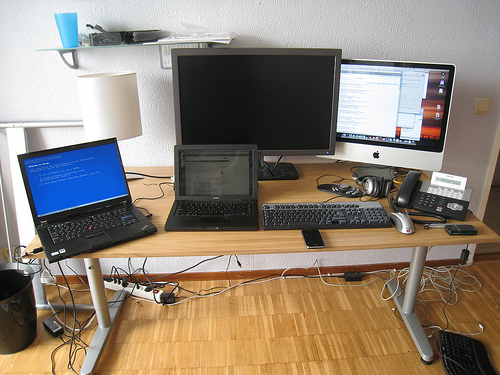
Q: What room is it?
A: It is an office.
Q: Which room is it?
A: It is an office.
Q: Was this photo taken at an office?
A: Yes, it was taken in an office.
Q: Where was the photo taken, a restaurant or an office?
A: It was taken at an office.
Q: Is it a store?
A: No, it is an office.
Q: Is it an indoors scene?
A: Yes, it is indoors.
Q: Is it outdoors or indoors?
A: It is indoors.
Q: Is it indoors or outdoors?
A: It is indoors.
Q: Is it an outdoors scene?
A: No, it is indoors.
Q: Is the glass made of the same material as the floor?
A: No, the glass is made of plastic and the floor is made of wood.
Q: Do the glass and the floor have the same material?
A: No, the glass is made of plastic and the floor is made of wood.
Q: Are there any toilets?
A: No, there are no toilets.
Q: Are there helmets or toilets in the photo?
A: No, there are no toilets or helmets.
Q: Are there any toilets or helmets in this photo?
A: No, there are no toilets or helmets.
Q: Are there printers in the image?
A: No, there are no printers.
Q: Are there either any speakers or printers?
A: No, there are no printers or speakers.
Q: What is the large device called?
A: The device is a monitor.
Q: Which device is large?
A: The device is a monitor.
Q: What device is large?
A: The device is a monitor.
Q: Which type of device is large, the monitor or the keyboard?
A: The monitor is large.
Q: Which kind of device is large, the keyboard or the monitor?
A: The monitor is large.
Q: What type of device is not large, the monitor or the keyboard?
A: The keyboard is not large.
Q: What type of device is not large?
A: The device is a keyboard.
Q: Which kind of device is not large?
A: The device is a keyboard.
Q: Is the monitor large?
A: Yes, the monitor is large.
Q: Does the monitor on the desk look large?
A: Yes, the monitor is large.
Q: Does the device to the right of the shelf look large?
A: Yes, the monitor is large.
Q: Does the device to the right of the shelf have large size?
A: Yes, the monitor is large.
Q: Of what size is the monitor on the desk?
A: The monitor is large.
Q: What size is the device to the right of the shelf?
A: The monitor is large.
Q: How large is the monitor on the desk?
A: The monitor is large.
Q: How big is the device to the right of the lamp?
A: The monitor is large.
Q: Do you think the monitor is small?
A: No, the monitor is large.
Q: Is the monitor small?
A: No, the monitor is large.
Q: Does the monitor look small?
A: No, the monitor is large.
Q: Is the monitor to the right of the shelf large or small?
A: The monitor is large.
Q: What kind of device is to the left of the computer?
A: The device is a monitor.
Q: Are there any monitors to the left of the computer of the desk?
A: Yes, there is a monitor to the left of the computer.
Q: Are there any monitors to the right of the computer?
A: No, the monitor is to the left of the computer.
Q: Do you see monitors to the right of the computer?
A: No, the monitor is to the left of the computer.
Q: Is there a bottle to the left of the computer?
A: No, there is a monitor to the left of the computer.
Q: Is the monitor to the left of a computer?
A: Yes, the monitor is to the left of a computer.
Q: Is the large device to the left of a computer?
A: Yes, the monitor is to the left of a computer.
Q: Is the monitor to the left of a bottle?
A: No, the monitor is to the left of a computer.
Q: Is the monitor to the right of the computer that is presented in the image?
A: No, the monitor is to the left of the computer.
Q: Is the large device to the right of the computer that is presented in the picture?
A: No, the monitor is to the left of the computer.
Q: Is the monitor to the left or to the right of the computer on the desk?
A: The monitor is to the left of the computer.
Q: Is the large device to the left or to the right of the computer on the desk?
A: The monitor is to the left of the computer.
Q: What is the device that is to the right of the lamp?
A: The device is a monitor.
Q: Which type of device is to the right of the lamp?
A: The device is a monitor.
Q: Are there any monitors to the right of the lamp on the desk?
A: Yes, there is a monitor to the right of the lamp.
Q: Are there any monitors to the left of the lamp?
A: No, the monitor is to the right of the lamp.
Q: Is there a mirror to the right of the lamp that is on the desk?
A: No, there is a monitor to the right of the lamp.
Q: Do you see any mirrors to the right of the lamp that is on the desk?
A: No, there is a monitor to the right of the lamp.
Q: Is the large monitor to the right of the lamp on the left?
A: Yes, the monitor is to the right of the lamp.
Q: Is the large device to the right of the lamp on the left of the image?
A: Yes, the monitor is to the right of the lamp.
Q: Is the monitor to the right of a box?
A: No, the monitor is to the right of the lamp.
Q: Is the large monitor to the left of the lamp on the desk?
A: No, the monitor is to the right of the lamp.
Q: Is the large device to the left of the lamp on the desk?
A: No, the monitor is to the right of the lamp.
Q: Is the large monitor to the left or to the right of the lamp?
A: The monitor is to the right of the lamp.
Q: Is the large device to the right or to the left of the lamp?
A: The monitor is to the right of the lamp.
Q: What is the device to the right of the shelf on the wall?
A: The device is a monitor.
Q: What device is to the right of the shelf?
A: The device is a monitor.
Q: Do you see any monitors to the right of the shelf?
A: Yes, there is a monitor to the right of the shelf.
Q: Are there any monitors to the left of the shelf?
A: No, the monitor is to the right of the shelf.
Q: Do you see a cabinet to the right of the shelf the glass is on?
A: No, there is a monitor to the right of the shelf.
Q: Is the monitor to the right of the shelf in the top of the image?
A: Yes, the monitor is to the right of the shelf.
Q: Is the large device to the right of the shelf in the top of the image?
A: Yes, the monitor is to the right of the shelf.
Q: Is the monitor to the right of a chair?
A: No, the monitor is to the right of the shelf.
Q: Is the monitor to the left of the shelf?
A: No, the monitor is to the right of the shelf.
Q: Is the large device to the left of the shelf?
A: No, the monitor is to the right of the shelf.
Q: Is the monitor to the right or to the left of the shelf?
A: The monitor is to the right of the shelf.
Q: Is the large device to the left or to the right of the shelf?
A: The monitor is to the right of the shelf.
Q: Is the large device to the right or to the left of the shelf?
A: The monitor is to the right of the shelf.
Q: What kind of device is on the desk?
A: The device is a monitor.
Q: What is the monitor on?
A: The monitor is on the desk.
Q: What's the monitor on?
A: The monitor is on the desk.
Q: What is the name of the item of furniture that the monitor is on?
A: The piece of furniture is a desk.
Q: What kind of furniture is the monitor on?
A: The monitor is on the desk.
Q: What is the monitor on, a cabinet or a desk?
A: The monitor is on a desk.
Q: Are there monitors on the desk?
A: Yes, there is a monitor on the desk.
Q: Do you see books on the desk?
A: No, there is a monitor on the desk.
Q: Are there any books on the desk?
A: No, there is a monitor on the desk.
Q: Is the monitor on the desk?
A: Yes, the monitor is on the desk.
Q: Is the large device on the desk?
A: Yes, the monitor is on the desk.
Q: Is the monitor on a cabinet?
A: No, the monitor is on the desk.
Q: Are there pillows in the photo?
A: No, there are no pillows.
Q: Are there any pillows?
A: No, there are no pillows.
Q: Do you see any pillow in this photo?
A: No, there are no pillows.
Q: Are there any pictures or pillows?
A: No, there are no pillows or pictures.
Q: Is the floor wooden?
A: Yes, the floor is wooden.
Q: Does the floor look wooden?
A: Yes, the floor is wooden.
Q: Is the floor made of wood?
A: Yes, the floor is made of wood.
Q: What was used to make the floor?
A: The floor is made of wood.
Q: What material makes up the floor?
A: The floor is made of wood.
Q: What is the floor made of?
A: The floor is made of wood.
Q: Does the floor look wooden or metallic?
A: The floor is wooden.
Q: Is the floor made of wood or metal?
A: The floor is made of wood.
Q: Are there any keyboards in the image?
A: Yes, there is a keyboard.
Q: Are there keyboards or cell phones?
A: Yes, there is a keyboard.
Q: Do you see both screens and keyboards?
A: Yes, there are both a keyboard and a screen.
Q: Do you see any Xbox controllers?
A: No, there are no Xbox controllers.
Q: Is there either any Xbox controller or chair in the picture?
A: No, there are no Xbox controllers or chairs.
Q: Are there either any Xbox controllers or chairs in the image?
A: No, there are no Xbox controllers or chairs.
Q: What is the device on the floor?
A: The device is a keyboard.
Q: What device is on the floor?
A: The device is a keyboard.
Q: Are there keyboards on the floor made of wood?
A: Yes, there is a keyboard on the floor.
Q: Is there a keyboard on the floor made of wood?
A: Yes, there is a keyboard on the floor.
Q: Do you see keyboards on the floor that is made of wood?
A: Yes, there is a keyboard on the floor.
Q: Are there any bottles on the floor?
A: No, there is a keyboard on the floor.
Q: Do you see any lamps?
A: Yes, there is a lamp.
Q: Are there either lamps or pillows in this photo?
A: Yes, there is a lamp.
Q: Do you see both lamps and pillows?
A: No, there is a lamp but no pillows.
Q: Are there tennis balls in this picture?
A: No, there are no tennis balls.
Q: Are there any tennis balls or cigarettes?
A: No, there are no tennis balls or cigarettes.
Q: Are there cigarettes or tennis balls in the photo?
A: No, there are no tennis balls or cigarettes.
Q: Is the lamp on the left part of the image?
A: Yes, the lamp is on the left of the image.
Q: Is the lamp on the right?
A: No, the lamp is on the left of the image.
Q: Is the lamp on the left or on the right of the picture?
A: The lamp is on the left of the image.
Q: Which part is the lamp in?
A: The lamp is on the left of the image.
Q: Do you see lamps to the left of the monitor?
A: Yes, there is a lamp to the left of the monitor.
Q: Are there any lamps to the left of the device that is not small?
A: Yes, there is a lamp to the left of the monitor.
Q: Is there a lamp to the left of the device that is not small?
A: Yes, there is a lamp to the left of the monitor.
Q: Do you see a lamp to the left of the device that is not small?
A: Yes, there is a lamp to the left of the monitor.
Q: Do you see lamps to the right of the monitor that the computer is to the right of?
A: No, the lamp is to the left of the monitor.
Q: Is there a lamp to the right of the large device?
A: No, the lamp is to the left of the monitor.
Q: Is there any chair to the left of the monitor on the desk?
A: No, there is a lamp to the left of the monitor.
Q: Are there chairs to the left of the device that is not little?
A: No, there is a lamp to the left of the monitor.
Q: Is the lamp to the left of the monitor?
A: Yes, the lamp is to the left of the monitor.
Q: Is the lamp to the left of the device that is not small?
A: Yes, the lamp is to the left of the monitor.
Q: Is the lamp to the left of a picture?
A: No, the lamp is to the left of the monitor.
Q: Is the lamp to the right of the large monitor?
A: No, the lamp is to the left of the monitor.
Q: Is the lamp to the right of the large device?
A: No, the lamp is to the left of the monitor.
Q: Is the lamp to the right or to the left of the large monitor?
A: The lamp is to the left of the monitor.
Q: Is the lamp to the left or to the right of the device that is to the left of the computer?
A: The lamp is to the left of the monitor.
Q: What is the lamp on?
A: The lamp is on the desk.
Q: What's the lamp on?
A: The lamp is on the desk.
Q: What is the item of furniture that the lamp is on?
A: The piece of furniture is a desk.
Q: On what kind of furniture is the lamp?
A: The lamp is on the desk.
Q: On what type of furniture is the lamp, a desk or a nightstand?
A: The lamp is on a desk.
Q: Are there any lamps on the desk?
A: Yes, there is a lamp on the desk.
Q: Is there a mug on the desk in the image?
A: No, there is a lamp on the desk.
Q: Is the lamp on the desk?
A: Yes, the lamp is on the desk.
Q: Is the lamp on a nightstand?
A: No, the lamp is on the desk.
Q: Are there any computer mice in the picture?
A: Yes, there is a computer mouse.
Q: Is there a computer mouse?
A: Yes, there is a computer mouse.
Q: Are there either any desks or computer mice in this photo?
A: Yes, there is a computer mouse.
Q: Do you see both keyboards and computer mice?
A: Yes, there are both a computer mouse and a keyboard.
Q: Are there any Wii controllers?
A: No, there are no Wii controllers.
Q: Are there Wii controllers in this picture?
A: No, there are no Wii controllers.